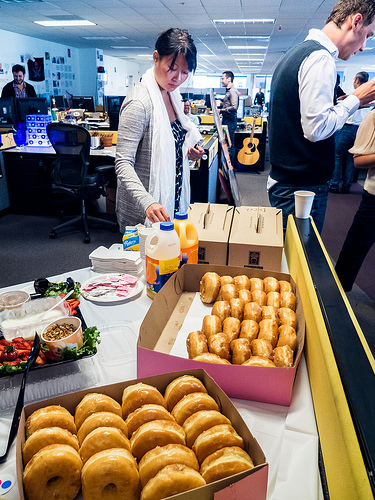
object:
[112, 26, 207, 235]
woman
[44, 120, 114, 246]
desk chair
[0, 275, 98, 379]
black tray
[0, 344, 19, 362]
strawberries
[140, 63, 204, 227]
scarf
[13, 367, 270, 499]
box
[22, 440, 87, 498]
doughnut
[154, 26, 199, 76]
hair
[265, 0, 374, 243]
man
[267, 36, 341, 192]
dark vest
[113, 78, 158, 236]
sweater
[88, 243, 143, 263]
napkins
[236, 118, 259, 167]
guitar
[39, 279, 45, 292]
black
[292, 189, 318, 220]
cup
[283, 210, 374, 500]
rail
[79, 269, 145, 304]
plate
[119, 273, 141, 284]
sugar packet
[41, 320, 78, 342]
food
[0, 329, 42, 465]
tongs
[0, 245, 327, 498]
table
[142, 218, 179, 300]
bottle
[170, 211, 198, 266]
bottle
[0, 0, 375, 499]
office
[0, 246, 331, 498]
tablecloth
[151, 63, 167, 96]
neck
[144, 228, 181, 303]
juice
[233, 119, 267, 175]
desk